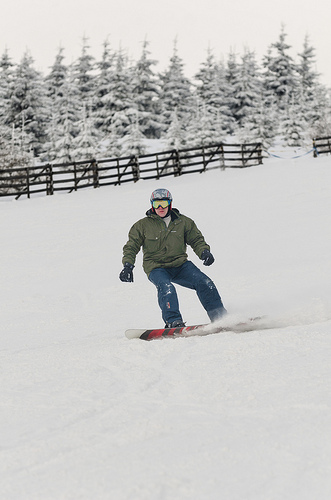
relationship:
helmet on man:
[129, 186, 178, 200] [118, 186, 242, 356]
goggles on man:
[154, 197, 178, 203] [118, 186, 242, 356]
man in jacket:
[118, 186, 242, 356] [135, 212, 201, 265]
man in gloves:
[118, 186, 242, 356] [202, 249, 219, 278]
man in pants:
[118, 186, 242, 356] [149, 267, 232, 314]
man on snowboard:
[118, 186, 242, 356] [130, 315, 280, 339]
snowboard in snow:
[130, 315, 280, 339] [180, 451, 302, 483]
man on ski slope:
[118, 186, 242, 356] [16, 275, 89, 326]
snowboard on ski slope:
[130, 315, 280, 339] [16, 275, 89, 326]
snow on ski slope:
[180, 451, 302, 483] [16, 275, 89, 326]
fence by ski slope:
[89, 164, 185, 180] [16, 275, 89, 326]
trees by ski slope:
[11, 58, 330, 120] [16, 275, 89, 326]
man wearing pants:
[118, 186, 242, 356] [149, 267, 232, 314]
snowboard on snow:
[130, 315, 280, 339] [180, 451, 302, 483]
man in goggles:
[118, 186, 242, 356] [154, 197, 178, 203]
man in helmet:
[118, 186, 242, 356] [129, 186, 178, 200]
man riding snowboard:
[118, 186, 242, 356] [130, 315, 280, 339]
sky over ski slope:
[236, 9, 287, 14] [16, 275, 89, 326]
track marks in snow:
[116, 347, 176, 400] [180, 451, 302, 483]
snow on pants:
[180, 451, 302, 483] [149, 267, 232, 314]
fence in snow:
[89, 164, 185, 180] [180, 451, 302, 483]